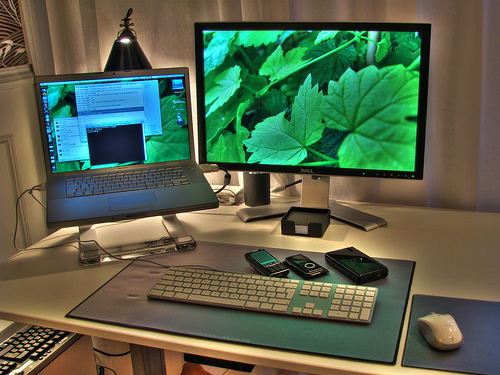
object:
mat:
[66, 235, 420, 365]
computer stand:
[66, 211, 200, 267]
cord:
[11, 176, 42, 256]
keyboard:
[0, 318, 76, 373]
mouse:
[415, 312, 461, 353]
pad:
[399, 286, 498, 375]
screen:
[35, 74, 192, 176]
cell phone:
[244, 247, 290, 278]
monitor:
[194, 22, 434, 176]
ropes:
[412, 306, 465, 353]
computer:
[191, 18, 431, 240]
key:
[300, 289, 309, 296]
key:
[305, 302, 315, 308]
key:
[312, 308, 323, 316]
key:
[303, 308, 313, 315]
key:
[292, 306, 304, 315]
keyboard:
[148, 266, 379, 324]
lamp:
[98, 23, 155, 71]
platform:
[68, 209, 196, 266]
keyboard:
[56, 164, 193, 198]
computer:
[32, 66, 226, 229]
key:
[268, 297, 290, 305]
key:
[256, 290, 267, 296]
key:
[228, 282, 238, 287]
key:
[200, 284, 210, 289]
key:
[283, 282, 297, 288]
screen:
[251, 250, 274, 268]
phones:
[325, 237, 389, 286]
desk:
[0, 152, 496, 370]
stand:
[282, 172, 331, 237]